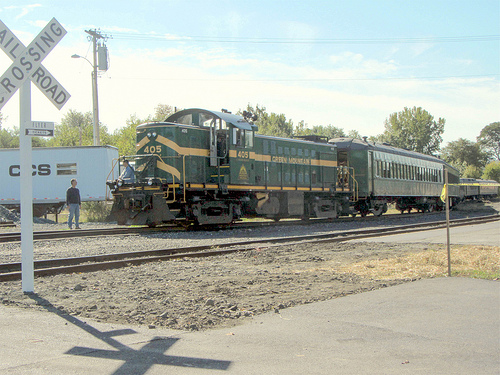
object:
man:
[66, 178, 82, 229]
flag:
[440, 183, 447, 203]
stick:
[444, 168, 451, 276]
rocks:
[122, 271, 224, 318]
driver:
[113, 160, 134, 185]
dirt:
[0, 258, 421, 329]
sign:
[0, 16, 72, 112]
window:
[377, 161, 379, 176]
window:
[383, 161, 386, 177]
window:
[387, 162, 389, 178]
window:
[244, 130, 254, 149]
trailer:
[0, 144, 119, 205]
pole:
[19, 78, 35, 295]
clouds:
[204, 52, 272, 77]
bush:
[367, 106, 446, 154]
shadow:
[26, 292, 230, 375]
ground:
[0, 275, 496, 375]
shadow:
[140, 203, 500, 240]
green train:
[105, 105, 500, 228]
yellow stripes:
[135, 134, 354, 191]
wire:
[110, 74, 496, 80]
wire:
[107, 33, 498, 43]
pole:
[70, 27, 114, 147]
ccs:
[9, 164, 51, 176]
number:
[144, 145, 162, 153]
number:
[238, 151, 249, 159]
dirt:
[1, 217, 63, 230]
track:
[0, 208, 454, 243]